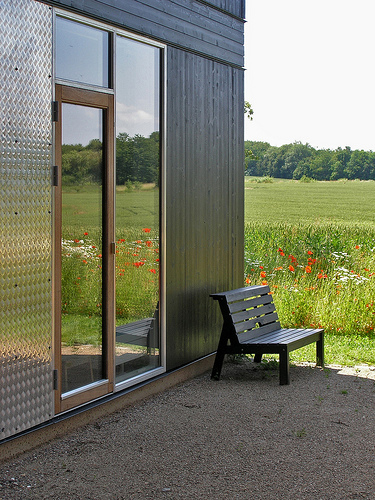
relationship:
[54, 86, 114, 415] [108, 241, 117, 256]
door has handle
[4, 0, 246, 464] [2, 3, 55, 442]
home with metal surface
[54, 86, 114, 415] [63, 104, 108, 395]
door has glass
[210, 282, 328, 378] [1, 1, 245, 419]
bench by building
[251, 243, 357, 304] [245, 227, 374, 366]
flowers in grass